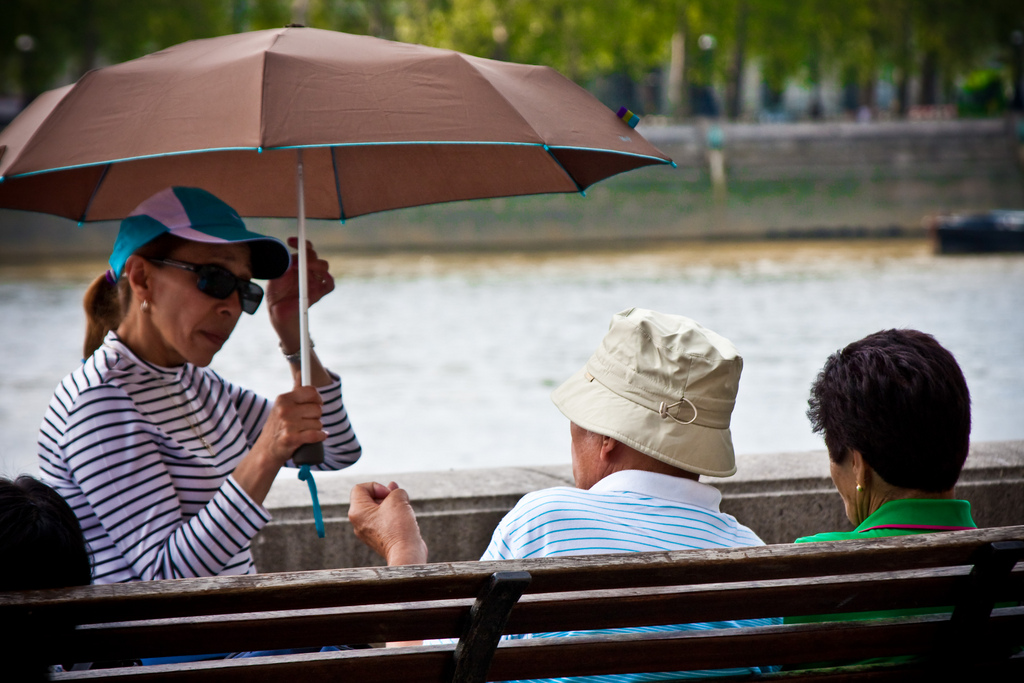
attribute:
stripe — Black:
[67, 386, 125, 419]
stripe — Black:
[62, 397, 133, 429]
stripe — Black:
[70, 435, 141, 464]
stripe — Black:
[219, 476, 276, 524]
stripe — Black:
[207, 484, 255, 539]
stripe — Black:
[191, 511, 233, 565]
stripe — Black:
[172, 519, 218, 573]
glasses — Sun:
[156, 242, 268, 313]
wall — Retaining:
[0, 112, 1024, 220]